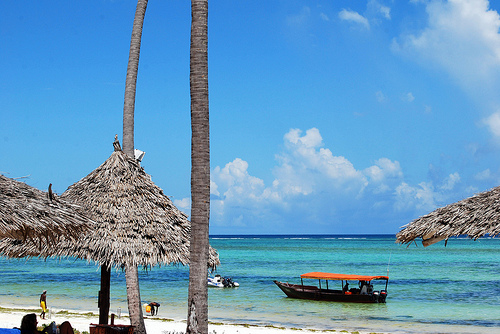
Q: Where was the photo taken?
A: It was taken at the ocean.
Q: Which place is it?
A: It is an ocean.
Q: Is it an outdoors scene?
A: Yes, it is outdoors.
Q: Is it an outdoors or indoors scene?
A: It is outdoors.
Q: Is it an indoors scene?
A: No, it is outdoors.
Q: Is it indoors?
A: No, it is outdoors.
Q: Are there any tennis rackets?
A: No, there are no tennis rackets.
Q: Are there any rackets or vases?
A: No, there are no rackets or vases.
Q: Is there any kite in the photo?
A: No, there are no kites.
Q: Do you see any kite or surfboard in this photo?
A: No, there are no kites or surfboards.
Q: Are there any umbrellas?
A: Yes, there is an umbrella.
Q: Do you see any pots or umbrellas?
A: Yes, there is an umbrella.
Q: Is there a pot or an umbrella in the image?
A: Yes, there is an umbrella.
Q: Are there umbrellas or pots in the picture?
A: Yes, there is an umbrella.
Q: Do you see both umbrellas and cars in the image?
A: No, there is an umbrella but no cars.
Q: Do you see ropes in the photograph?
A: No, there are no ropes.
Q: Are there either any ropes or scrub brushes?
A: No, there are no ropes or scrub brushes.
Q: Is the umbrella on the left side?
A: Yes, the umbrella is on the left of the image.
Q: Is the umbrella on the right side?
A: No, the umbrella is on the left of the image.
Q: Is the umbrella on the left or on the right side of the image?
A: The umbrella is on the left of the image.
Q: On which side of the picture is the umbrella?
A: The umbrella is on the left of the image.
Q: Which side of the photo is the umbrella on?
A: The umbrella is on the left of the image.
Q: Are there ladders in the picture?
A: No, there are no ladders.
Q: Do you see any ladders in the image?
A: No, there are no ladders.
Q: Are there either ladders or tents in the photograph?
A: No, there are no ladders or tents.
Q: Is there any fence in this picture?
A: No, there are no fences.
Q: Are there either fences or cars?
A: No, there are no fences or cars.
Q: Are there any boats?
A: Yes, there is a boat.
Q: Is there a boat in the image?
A: Yes, there is a boat.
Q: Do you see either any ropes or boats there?
A: Yes, there is a boat.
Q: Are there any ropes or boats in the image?
A: Yes, there is a boat.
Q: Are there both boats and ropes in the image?
A: No, there is a boat but no ropes.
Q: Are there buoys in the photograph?
A: No, there are no buoys.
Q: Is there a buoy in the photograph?
A: No, there are no buoys.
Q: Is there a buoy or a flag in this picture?
A: No, there are no buoys or flags.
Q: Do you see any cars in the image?
A: No, there are no cars.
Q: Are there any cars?
A: No, there are no cars.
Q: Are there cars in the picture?
A: No, there are no cars.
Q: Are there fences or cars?
A: No, there are no cars or fences.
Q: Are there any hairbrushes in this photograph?
A: No, there are no hairbrushes.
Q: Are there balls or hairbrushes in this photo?
A: No, there are no hairbrushes or balls.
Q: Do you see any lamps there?
A: No, there are no lamps.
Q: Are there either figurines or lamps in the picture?
A: No, there are no lamps or figurines.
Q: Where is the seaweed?
A: The seaweed is on the shore.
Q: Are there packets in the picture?
A: No, there are no packets.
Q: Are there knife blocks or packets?
A: No, there are no packets or knife blocks.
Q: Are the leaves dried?
A: Yes, the leaves are dried.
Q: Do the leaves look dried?
A: Yes, the leaves are dried.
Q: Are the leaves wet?
A: No, the leaves are dried.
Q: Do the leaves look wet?
A: No, the leaves are dried.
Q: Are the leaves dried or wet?
A: The leaves are dried.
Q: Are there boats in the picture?
A: Yes, there is a boat.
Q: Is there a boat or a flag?
A: Yes, there is a boat.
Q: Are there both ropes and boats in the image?
A: No, there is a boat but no ropes.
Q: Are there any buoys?
A: No, there are no buoys.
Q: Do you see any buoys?
A: No, there are no buoys.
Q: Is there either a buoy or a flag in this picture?
A: No, there are no buoys or flags.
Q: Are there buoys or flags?
A: No, there are no buoys or flags.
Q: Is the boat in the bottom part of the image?
A: Yes, the boat is in the bottom of the image.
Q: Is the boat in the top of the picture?
A: No, the boat is in the bottom of the image.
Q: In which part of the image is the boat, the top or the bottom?
A: The boat is in the bottom of the image.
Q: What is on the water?
A: The boat is on the water.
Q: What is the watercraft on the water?
A: The watercraft is a boat.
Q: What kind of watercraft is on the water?
A: The watercraft is a boat.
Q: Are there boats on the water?
A: Yes, there is a boat on the water.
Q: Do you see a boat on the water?
A: Yes, there is a boat on the water.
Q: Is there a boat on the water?
A: Yes, there is a boat on the water.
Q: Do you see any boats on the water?
A: Yes, there is a boat on the water.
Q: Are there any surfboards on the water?
A: No, there is a boat on the water.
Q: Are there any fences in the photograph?
A: No, there are no fences.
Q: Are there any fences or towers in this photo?
A: No, there are no fences or towers.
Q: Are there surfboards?
A: No, there are no surfboards.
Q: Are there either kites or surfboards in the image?
A: No, there are no surfboards or kites.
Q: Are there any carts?
A: No, there are no carts.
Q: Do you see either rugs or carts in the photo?
A: No, there are no carts or rugs.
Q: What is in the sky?
A: The clouds are in the sky.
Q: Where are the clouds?
A: The clouds are in the sky.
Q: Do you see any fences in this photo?
A: No, there are no fences.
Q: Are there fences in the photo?
A: No, there are no fences.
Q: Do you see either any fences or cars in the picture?
A: No, there are no fences or cars.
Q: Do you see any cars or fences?
A: No, there are no fences or cars.